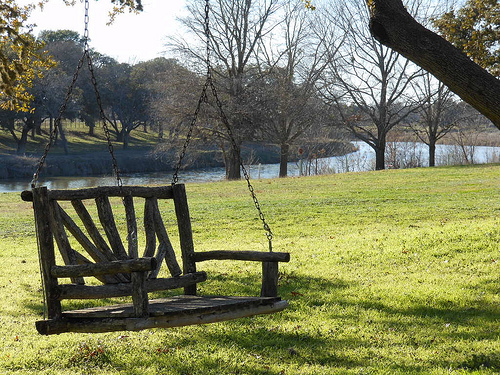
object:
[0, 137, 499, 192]
river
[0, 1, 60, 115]
trees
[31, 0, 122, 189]
chains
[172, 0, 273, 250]
chain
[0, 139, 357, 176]
bank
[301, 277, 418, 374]
shadows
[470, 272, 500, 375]
shadow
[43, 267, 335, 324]
shadows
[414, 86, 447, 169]
tree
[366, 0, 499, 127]
branch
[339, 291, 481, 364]
grass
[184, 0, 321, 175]
sbare tree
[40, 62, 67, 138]
tree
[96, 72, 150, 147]
tree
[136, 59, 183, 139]
tree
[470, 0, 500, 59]
tree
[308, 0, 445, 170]
tree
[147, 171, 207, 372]
ground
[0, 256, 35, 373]
grass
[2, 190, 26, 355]
ground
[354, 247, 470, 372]
ground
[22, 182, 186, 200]
wooden post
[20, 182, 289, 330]
bench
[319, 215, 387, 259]
grass